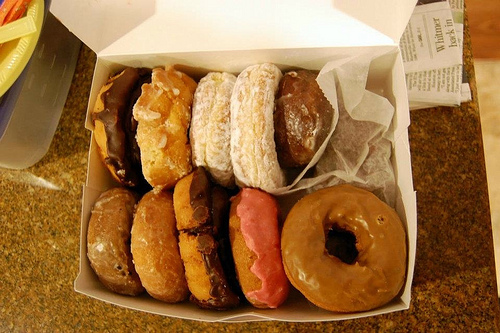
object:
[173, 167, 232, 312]
dough nut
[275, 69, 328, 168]
nut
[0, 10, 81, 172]
bucket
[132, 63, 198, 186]
dough nugt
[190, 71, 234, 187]
donut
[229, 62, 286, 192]
donut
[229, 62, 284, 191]
doughnuts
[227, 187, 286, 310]
doughnut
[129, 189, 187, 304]
doughnut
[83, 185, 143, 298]
doughnut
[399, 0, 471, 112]
newspaper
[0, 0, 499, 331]
counter-top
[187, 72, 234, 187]
dough nut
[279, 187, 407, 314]
donut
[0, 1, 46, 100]
cover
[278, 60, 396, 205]
paper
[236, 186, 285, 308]
pink frosting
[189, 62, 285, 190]
powder/icing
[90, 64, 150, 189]
frosting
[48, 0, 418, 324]
box